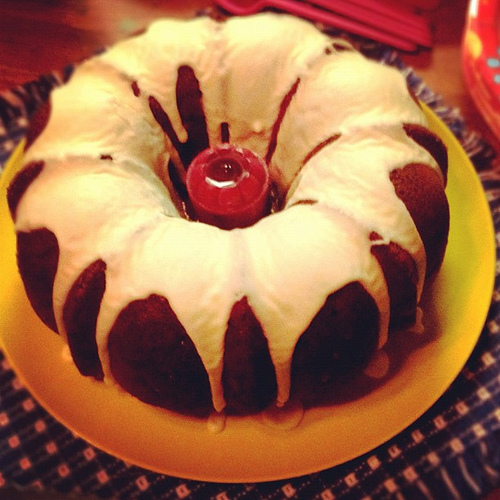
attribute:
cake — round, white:
[13, 15, 439, 397]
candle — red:
[181, 127, 278, 229]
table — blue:
[17, 375, 478, 493]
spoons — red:
[231, 0, 433, 55]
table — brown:
[4, 8, 499, 176]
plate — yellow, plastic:
[8, 119, 498, 487]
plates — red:
[459, 12, 499, 139]